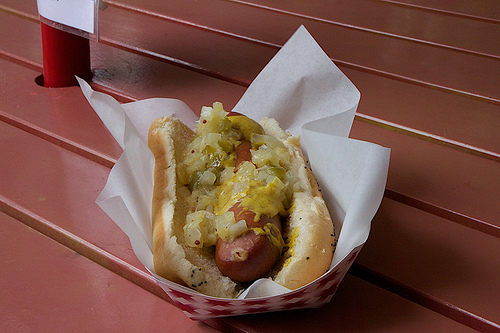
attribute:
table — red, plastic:
[12, 7, 491, 326]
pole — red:
[40, 0, 102, 87]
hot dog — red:
[154, 109, 336, 298]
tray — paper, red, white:
[134, 243, 358, 314]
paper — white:
[235, 22, 356, 127]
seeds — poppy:
[182, 266, 216, 291]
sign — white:
[32, 0, 103, 44]